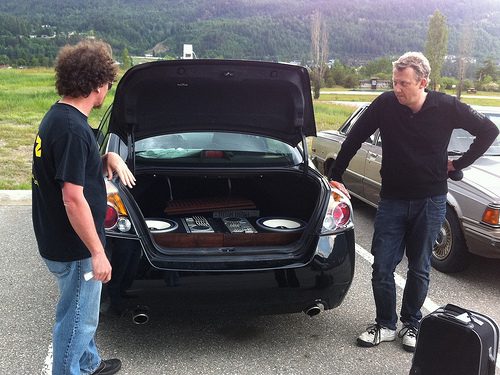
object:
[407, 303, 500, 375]
luggage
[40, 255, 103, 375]
jeans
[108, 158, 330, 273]
black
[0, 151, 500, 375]
ground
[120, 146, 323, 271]
trunk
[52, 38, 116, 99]
curly hair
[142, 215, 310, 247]
speaker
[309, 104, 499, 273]
car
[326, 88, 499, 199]
dark shirt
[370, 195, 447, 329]
blue jeans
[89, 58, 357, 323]
black car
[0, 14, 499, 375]
public place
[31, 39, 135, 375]
friend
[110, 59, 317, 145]
lid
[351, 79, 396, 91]
building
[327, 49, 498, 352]
guy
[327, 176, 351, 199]
hand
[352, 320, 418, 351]
shoes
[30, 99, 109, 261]
shirt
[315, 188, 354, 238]
taillights